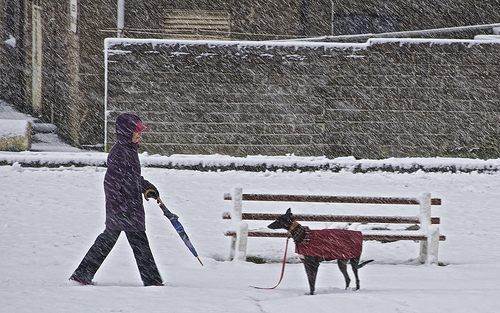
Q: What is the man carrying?
A: An umbrella.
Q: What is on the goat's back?
A: A red cloth.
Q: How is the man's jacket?
A: Hooded.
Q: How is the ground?
A: Snowed.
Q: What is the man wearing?
A: A red cap.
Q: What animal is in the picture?
A: Dog.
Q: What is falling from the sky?
A: Snow.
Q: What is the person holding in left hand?
A: Umbrella.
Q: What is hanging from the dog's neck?
A: Leash.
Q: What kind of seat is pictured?
A: Bench.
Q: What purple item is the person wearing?
A: Coat.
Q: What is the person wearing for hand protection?
A: Gloves.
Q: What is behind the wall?
A: Building.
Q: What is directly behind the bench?
A: Wall.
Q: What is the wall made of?
A: Bricks.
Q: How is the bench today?
A: Covered in snow.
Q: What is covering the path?
A: Snow.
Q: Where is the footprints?
A: In the snow.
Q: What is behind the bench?
A: A wall.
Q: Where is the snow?
A: Top of the wall.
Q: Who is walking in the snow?
A: A woman.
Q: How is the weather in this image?
A: Snowing.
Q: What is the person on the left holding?
A: Umbrella.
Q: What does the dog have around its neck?
A: Leash.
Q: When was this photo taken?
A: During the day.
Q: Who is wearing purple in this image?
A: The human.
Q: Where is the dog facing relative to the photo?
A: Left.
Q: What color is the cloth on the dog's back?
A: Red.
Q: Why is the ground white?
A: Covered in snow.